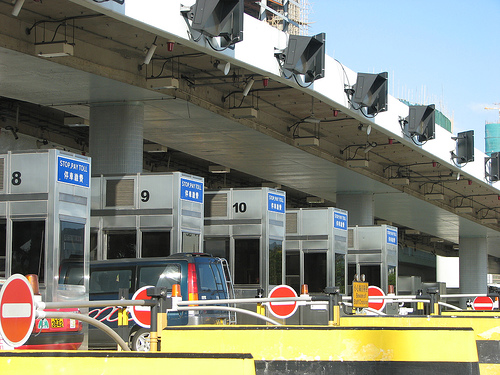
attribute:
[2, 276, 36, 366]
sign — red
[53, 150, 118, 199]
sign — blue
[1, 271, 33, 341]
sign — red, white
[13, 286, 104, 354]
car — red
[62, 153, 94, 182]
sign — blue, white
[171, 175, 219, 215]
sign — white, blue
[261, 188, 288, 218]
sign — blue, white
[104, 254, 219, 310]
vehicle — dark colored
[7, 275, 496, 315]
signs — round, red, white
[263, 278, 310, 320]
sign — white, red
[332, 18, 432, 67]
sky — clear, blue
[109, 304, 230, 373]
lanes — yellow, construction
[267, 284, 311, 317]
sign — red, white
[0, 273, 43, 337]
sign — circle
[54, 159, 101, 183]
sign — blue, white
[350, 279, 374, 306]
sign — yellow, black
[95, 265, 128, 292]
window — side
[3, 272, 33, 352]
sign — red, white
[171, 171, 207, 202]
sign — blue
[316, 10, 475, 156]
sky — light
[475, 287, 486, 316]
sign — circular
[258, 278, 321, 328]
sign — circular